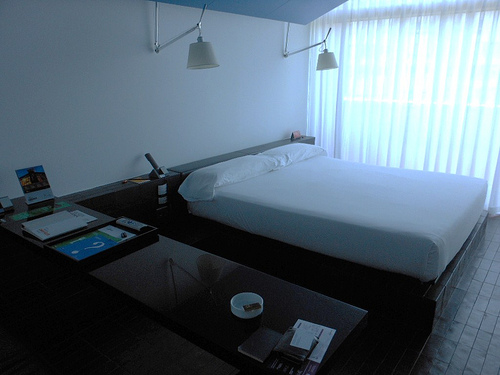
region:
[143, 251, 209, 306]
table is black in color.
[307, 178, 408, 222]
bed spread is white in color.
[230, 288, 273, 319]
bowl is white in color.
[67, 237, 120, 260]
file is blue in color.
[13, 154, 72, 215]
calender is kept in the table.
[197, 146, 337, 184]
two pillows are in cot.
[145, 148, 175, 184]
remote is black in color.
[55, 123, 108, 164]
wall is white in color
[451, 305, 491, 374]
floor is grey in color.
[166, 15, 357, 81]
two lamps are hanging in the wall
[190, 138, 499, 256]
this is a bed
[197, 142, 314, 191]
the pillows are white in color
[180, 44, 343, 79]
two lamps on the wall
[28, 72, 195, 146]
the wall is white in color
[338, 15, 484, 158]
the curtains are closed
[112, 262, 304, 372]
this is a table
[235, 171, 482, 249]
the matress has white sheets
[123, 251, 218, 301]
the table is black in color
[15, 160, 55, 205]
this is a calender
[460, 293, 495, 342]
the floor is black in color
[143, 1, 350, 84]
two over head lamps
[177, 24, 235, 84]
a small white lamp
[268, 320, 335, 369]
a thick black wallet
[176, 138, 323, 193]
two pillows in white pillow cases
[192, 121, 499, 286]
a bed with white sheets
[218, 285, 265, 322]
a small white bowl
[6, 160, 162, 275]
an assortment of information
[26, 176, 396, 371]
a long black table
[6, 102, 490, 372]
a scene of a hotel room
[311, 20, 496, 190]
sheer white curtains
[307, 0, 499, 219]
The window is bright and sunny.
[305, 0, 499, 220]
The window has a white sheer curtain hanging on it.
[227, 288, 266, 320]
An unused ashtray with a book of matches in it is sitting on the desk.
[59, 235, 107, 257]
A blue brochure with a white question mark is sitting on the desk.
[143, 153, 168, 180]
A cordless phone is on the headboard beside the bed.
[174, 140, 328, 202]
Two pillows with white pillow cases are on the bed.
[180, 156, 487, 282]
The bed is made neatly with a white sheet.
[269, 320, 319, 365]
A man's black wallet is sitting on the desk.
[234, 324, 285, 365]
A man's black book of numbers is sitting on the desk.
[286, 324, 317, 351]
A white business card is sitting on top of the wallet.